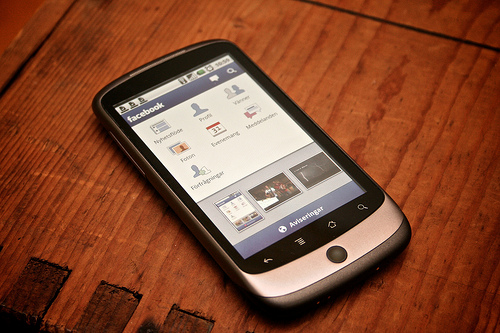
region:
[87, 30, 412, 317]
black and silver smart phone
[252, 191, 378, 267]
buttons at the bottom of a smart phone screen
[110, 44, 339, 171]
facebook app on a smart phone screen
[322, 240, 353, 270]
round microphone on a smart phone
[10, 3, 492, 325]
wooden table with smart phone laying on it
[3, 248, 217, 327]
dark patches in a wooden table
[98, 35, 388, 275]
black frame around smart phone screen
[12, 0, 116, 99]
dark area in a brown wood table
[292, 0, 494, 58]
black separation line in wood table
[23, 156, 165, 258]
light scratches in a wood table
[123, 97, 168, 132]
the facebook icon on a cell phone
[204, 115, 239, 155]
calendar application on a cell phone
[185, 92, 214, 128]
profile icon on a cell phone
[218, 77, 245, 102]
friend icon on a cell phone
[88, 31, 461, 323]
a cell phone opened up to facebook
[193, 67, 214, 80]
battery icon on a cell phone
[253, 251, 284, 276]
back button on a cell phone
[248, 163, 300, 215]
picture application on a cell phone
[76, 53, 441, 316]
black and silver cell phone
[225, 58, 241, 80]
search icon on a cell phone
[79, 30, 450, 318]
the phone is silver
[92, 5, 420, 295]
the phone is on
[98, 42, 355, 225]
the screen is on facebook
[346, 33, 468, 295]
the table is brown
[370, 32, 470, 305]
the table is made of wood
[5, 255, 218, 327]
dark marks in the table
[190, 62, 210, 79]
the battery life symbol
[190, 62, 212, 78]
the battery symbol is green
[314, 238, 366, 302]
a dark circle on the phone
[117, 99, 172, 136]
the letters are white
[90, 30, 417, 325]
A silver and black mobile phone.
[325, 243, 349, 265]
A black track pad button on a phone.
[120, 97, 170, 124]
A blue and white facebook logo.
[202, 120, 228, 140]
A red and white calendar icon.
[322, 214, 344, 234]
A mobile phone home button.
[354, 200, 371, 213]
A mobile phone search button.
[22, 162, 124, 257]
A patch of wood grain on a table.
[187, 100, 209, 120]
A profile button on a mobile phone.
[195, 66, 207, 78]
A green battery indicator on a phone.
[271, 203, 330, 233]
An Aviseringar logo.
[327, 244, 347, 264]
Microphone on bottom of cell phone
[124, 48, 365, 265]
Webpage image on cell phone screen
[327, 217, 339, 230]
Home button on cell phone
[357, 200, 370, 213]
Search button on cell phone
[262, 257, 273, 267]
Back button on cell phone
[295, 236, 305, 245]
Menu button on cell phone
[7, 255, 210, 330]
Wooden strips on edge of table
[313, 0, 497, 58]
Crack between wooden sections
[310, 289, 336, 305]
Auxilliary jack holes on cell phone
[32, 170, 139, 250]
Scratches in wood surface